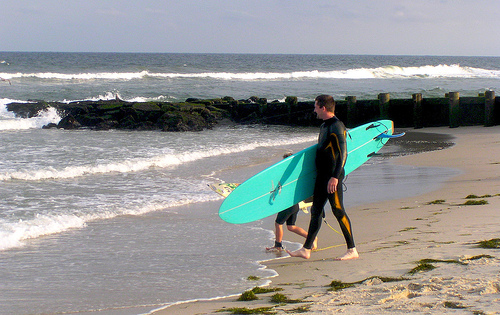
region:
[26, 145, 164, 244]
The waves on the beach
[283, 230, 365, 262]
The feet of the man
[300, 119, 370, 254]
The man has on a wet suit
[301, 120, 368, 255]
The wet suit is the color black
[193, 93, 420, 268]
The man is holding a surfboard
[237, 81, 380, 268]
The man is walking with a child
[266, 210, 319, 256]
The legs of the child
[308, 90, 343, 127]
The head of the man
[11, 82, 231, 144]
The rocks in the ocean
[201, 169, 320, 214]
The young person has a surfboard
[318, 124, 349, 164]
the suit is black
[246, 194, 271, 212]
the board is torquoise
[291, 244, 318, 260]
the man is barefoot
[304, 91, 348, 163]
the man is carring the board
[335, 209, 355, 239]
the design is yellow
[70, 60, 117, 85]
the water has waves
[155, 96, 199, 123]
the rocks have moss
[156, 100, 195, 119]
the rocks have seaweed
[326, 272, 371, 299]
the seaweed is on the beach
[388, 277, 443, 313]
the sand has tracks in it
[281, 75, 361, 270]
The man is wearing a wetsuit.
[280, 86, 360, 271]
The wetsuit is black and orange.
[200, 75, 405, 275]
The man is holding a surfboard.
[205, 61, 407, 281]
The man is walking.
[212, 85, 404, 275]
The surfboard is aqua in color.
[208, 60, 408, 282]
The man is barefoot.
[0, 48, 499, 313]
The water is wavy.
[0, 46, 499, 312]
The water is zealous.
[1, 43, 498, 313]
The water is spirited.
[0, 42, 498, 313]
The water is splashing.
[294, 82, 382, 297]
man is wearing a wetsuit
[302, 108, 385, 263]
man's wet suit is black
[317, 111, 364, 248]
yellow lines on wet suit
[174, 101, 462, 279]
man is holding a surfboard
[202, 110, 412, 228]
the surfboard is blue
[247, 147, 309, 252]
child walking on other side of board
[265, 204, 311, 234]
child is wearing shorts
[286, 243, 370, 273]
man has no shoes on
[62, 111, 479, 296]
the sand is wet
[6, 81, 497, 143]
rocks in the water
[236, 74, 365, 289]
a man carrying a surf board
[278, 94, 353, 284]
a man walking on a beach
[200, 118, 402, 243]
a green surf board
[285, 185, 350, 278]
a man with bare feet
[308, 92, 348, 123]
a man with short hair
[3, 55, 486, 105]
white waves in the ocean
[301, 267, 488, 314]
tracks in the sand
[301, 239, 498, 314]
tracks on a beach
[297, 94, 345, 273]
a man wearing a wetsuit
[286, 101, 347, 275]
a man wearing a black wet suit with yellow stripes